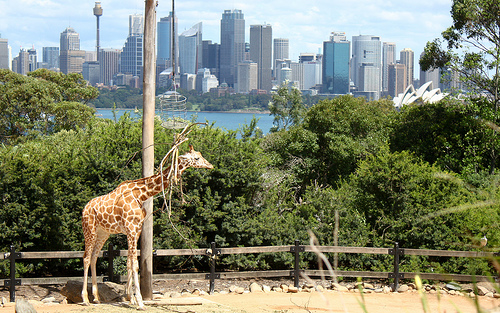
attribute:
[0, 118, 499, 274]
bushes — green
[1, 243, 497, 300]
fence — wooden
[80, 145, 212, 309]
giraffe — yellow  , brown  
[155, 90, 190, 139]
feeding basket — giraffe's feeding, elevated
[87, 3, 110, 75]
tower — large, slender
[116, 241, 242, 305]
basket — feeding 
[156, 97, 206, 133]
metal container — metal 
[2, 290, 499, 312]
ground — sandy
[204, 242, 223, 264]
reinforcement — metal 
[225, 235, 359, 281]
fence — wooden  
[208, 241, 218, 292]
post — metal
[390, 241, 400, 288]
support — brace